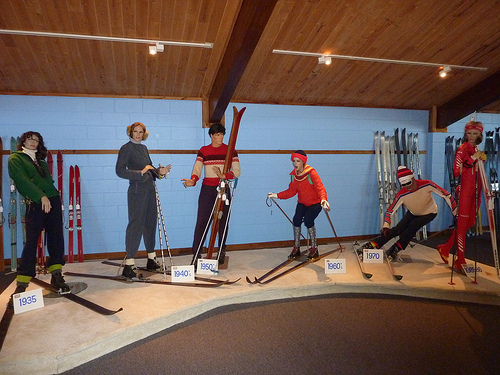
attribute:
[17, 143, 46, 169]
turtle neck — White 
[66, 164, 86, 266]
skis — red 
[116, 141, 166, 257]
one piece — grey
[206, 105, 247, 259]
skis — red 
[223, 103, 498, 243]
wall — Blue , brick 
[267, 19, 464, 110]
ceiling — brown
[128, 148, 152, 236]
clothes — grey 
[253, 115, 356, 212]
block wall — blue 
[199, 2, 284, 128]
beam — brown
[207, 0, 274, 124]
beam — dark 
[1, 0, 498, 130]
ceiling — wood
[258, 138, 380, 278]
mannequin — child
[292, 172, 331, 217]
jacket — orange